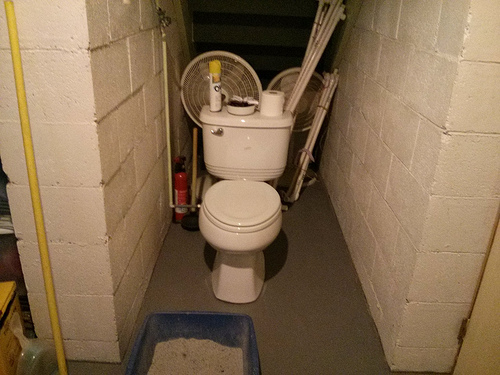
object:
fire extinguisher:
[171, 153, 192, 224]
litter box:
[122, 310, 273, 375]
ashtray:
[226, 101, 256, 116]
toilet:
[197, 104, 292, 303]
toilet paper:
[257, 90, 287, 118]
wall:
[32, 9, 158, 363]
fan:
[184, 51, 263, 130]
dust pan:
[3, 319, 54, 374]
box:
[0, 281, 29, 372]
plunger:
[180, 127, 204, 232]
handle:
[188, 125, 202, 209]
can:
[207, 58, 224, 112]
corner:
[16, 281, 79, 373]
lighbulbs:
[310, 10, 320, 38]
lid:
[204, 181, 280, 226]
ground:
[267, 255, 380, 374]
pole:
[4, 0, 69, 375]